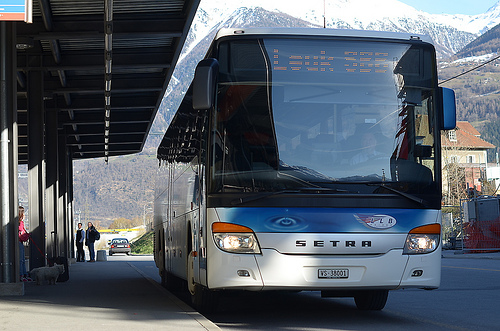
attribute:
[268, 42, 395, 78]
sing — electronic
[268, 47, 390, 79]
letters — orange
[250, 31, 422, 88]
sign — red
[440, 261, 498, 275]
paint — yellow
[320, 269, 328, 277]
letters — black